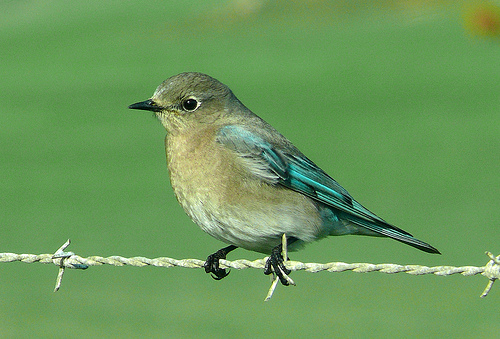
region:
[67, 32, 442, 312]
the bird is perched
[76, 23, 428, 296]
the bird is sitting on a wire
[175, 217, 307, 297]
the feet are black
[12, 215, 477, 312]
the wire is white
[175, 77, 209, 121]
the eye is open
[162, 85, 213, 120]
the eye is black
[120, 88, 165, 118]
the beak is black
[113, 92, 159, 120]
the beak is pointy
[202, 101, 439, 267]
the wings are green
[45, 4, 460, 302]
the background is green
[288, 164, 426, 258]
the tail is blue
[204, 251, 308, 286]
the legs are black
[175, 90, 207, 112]
the eyes are black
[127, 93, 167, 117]
the beak is black .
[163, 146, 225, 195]
the neck is brown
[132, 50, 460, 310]
the bird is perched on the wire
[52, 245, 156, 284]
the wires are barbed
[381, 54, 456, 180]
grass is in the background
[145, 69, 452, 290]
the bird is small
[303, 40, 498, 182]
the background is blurred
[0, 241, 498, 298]
top of a barbed wire fence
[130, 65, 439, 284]
little bird sitting on barbed wire fence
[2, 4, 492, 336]
blurry green grass behind the bird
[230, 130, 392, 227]
the bird's blue wing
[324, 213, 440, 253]
the bird's blue tail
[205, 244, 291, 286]
the little bird's black legs and feet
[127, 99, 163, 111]
the bird's black beak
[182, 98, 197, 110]
the bird's black left eye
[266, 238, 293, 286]
bird's left foot on a barb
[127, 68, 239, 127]
the bird's head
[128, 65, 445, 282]
bird on a wire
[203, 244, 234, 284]
foot holding wire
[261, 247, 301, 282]
foot on a wire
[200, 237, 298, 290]
feet on the wire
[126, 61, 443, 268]
bird sitting on a wire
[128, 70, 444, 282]
bird grasping wire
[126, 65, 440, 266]
blue and gray bird on wire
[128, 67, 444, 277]
blue and gray bird grasping wire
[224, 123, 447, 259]
blue feather on the bird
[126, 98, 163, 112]
beak on the bird